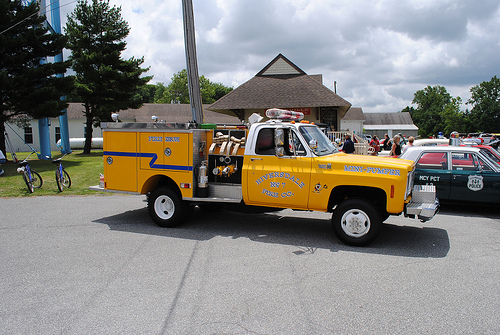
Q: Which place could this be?
A: It is a road.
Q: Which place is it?
A: It is a road.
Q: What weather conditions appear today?
A: It is cloudy.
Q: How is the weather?
A: It is cloudy.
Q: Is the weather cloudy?
A: Yes, it is cloudy.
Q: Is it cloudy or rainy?
A: It is cloudy.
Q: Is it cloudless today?
A: No, it is cloudy.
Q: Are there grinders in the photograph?
A: No, there are no grinders.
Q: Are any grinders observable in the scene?
A: No, there are no grinders.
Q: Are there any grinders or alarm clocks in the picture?
A: No, there are no grinders or alarm clocks.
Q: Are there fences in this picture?
A: No, there are no fences.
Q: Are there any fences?
A: No, there are no fences.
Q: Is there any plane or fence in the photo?
A: No, there are no fences or airplanes.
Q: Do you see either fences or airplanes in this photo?
A: No, there are no fences or airplanes.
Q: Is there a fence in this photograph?
A: No, there are no fences.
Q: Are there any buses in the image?
A: No, there are no buses.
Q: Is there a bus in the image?
A: No, there are no buses.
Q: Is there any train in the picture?
A: No, there are no trains.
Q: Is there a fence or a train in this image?
A: No, there are no trains or fences.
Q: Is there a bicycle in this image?
A: Yes, there is a bicycle.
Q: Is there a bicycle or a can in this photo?
A: Yes, there is a bicycle.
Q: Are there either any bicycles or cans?
A: Yes, there is a bicycle.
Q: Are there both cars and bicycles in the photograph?
A: Yes, there are both a bicycle and a car.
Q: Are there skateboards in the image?
A: No, there are no skateboards.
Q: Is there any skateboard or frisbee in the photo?
A: No, there are no skateboards or frisbees.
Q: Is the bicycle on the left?
A: Yes, the bicycle is on the left of the image.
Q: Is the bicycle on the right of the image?
A: No, the bicycle is on the left of the image.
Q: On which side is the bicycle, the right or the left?
A: The bicycle is on the left of the image.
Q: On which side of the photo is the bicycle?
A: The bicycle is on the left of the image.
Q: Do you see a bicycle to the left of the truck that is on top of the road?
A: Yes, there is a bicycle to the left of the truck.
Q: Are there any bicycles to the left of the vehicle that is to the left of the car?
A: Yes, there is a bicycle to the left of the truck.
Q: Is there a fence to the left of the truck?
A: No, there is a bicycle to the left of the truck.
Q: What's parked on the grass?
A: The bicycle is parked on the grass.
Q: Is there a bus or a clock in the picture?
A: No, there are no buses or clocks.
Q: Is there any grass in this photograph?
A: Yes, there is grass.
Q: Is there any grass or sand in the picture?
A: Yes, there is grass.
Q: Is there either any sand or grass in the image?
A: Yes, there is grass.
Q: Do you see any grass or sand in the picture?
A: Yes, there is grass.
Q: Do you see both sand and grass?
A: No, there is grass but no sand.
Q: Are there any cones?
A: No, there are no cones.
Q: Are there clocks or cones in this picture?
A: No, there are no cones or clocks.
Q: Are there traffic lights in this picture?
A: No, there are no traffic lights.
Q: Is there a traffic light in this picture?
A: No, there are no traffic lights.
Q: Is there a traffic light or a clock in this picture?
A: No, there are no traffic lights or clocks.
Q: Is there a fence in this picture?
A: No, there are no fences.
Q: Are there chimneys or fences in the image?
A: No, there are no fences or chimneys.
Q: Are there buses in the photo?
A: No, there are no buses.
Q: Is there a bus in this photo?
A: No, there are no buses.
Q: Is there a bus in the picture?
A: No, there are no buses.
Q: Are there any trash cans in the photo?
A: No, there are no trash cans.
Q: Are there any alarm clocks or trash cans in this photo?
A: No, there are no trash cans or alarm clocks.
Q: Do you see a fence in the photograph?
A: No, there are no fences.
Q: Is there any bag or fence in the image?
A: No, there are no fences or bags.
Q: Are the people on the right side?
A: Yes, the people are on the right of the image.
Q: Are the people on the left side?
A: No, the people are on the right of the image.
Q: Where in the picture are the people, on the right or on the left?
A: The people are on the right of the image.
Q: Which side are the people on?
A: The people are on the right of the image.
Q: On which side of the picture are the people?
A: The people are on the right of the image.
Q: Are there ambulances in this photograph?
A: No, there are no ambulances.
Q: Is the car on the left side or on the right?
A: The car is on the right of the image.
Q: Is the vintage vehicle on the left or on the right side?
A: The car is on the right of the image.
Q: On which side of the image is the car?
A: The car is on the right of the image.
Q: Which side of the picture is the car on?
A: The car is on the right of the image.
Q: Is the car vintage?
A: Yes, the car is vintage.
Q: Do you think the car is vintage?
A: Yes, the car is vintage.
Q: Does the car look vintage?
A: Yes, the car is vintage.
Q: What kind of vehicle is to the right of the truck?
A: The vehicle is a car.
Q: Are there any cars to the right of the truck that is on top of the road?
A: Yes, there is a car to the right of the truck.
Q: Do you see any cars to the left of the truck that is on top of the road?
A: No, the car is to the right of the truck.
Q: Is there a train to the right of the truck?
A: No, there is a car to the right of the truck.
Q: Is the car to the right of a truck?
A: Yes, the car is to the right of a truck.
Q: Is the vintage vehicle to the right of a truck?
A: Yes, the car is to the right of a truck.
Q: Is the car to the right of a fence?
A: No, the car is to the right of a truck.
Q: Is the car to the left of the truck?
A: No, the car is to the right of the truck.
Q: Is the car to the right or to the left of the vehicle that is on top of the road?
A: The car is to the right of the truck.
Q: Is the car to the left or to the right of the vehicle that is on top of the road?
A: The car is to the right of the truck.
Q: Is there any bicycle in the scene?
A: Yes, there is a bicycle.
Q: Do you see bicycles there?
A: Yes, there is a bicycle.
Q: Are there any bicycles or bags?
A: Yes, there is a bicycle.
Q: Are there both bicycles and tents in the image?
A: No, there is a bicycle but no tents.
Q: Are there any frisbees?
A: No, there are no frisbees.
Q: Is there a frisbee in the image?
A: No, there are no frisbees.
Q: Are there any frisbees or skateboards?
A: No, there are no frisbees or skateboards.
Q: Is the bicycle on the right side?
A: No, the bicycle is on the left of the image.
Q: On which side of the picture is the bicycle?
A: The bicycle is on the left of the image.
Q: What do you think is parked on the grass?
A: The bicycle is parked on the grass.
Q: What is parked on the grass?
A: The bicycle is parked on the grass.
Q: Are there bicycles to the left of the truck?
A: Yes, there is a bicycle to the left of the truck.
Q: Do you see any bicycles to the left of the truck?
A: Yes, there is a bicycle to the left of the truck.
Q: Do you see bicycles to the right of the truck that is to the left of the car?
A: No, the bicycle is to the left of the truck.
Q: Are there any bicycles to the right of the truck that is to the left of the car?
A: No, the bicycle is to the left of the truck.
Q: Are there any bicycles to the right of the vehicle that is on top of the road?
A: No, the bicycle is to the left of the truck.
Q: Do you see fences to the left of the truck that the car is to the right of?
A: No, there is a bicycle to the left of the truck.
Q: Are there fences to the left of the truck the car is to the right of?
A: No, there is a bicycle to the left of the truck.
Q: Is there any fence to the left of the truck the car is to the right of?
A: No, there is a bicycle to the left of the truck.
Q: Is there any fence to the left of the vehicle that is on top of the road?
A: No, there is a bicycle to the left of the truck.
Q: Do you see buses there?
A: No, there are no buses.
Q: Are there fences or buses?
A: No, there are no buses or fences.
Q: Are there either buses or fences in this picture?
A: No, there are no buses or fences.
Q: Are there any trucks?
A: Yes, there is a truck.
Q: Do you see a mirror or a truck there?
A: Yes, there is a truck.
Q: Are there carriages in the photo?
A: No, there are no carriages.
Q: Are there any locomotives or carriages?
A: No, there are no carriages or locomotives.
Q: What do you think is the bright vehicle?
A: The vehicle is a truck.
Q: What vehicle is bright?
A: The vehicle is a truck.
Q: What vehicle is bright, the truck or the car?
A: The truck is bright.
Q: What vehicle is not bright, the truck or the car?
A: The car is not bright.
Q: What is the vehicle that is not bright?
A: The vehicle is a car.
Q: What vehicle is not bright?
A: The vehicle is a car.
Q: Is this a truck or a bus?
A: This is a truck.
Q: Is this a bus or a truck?
A: This is a truck.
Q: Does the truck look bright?
A: Yes, the truck is bright.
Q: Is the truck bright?
A: Yes, the truck is bright.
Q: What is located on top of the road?
A: The truck is on top of the road.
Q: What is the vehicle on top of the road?
A: The vehicle is a truck.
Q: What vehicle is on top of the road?
A: The vehicle is a truck.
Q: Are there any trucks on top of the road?
A: Yes, there is a truck on top of the road.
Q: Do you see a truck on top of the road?
A: Yes, there is a truck on top of the road.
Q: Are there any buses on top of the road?
A: No, there is a truck on top of the road.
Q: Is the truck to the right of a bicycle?
A: Yes, the truck is to the right of a bicycle.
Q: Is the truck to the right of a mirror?
A: No, the truck is to the right of a bicycle.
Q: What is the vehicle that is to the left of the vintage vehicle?
A: The vehicle is a truck.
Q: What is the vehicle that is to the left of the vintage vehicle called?
A: The vehicle is a truck.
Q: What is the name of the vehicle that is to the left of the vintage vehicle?
A: The vehicle is a truck.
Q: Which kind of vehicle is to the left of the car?
A: The vehicle is a truck.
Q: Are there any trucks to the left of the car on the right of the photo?
A: Yes, there is a truck to the left of the car.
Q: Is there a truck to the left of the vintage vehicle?
A: Yes, there is a truck to the left of the car.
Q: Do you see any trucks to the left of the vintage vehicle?
A: Yes, there is a truck to the left of the car.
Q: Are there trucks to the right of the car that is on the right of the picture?
A: No, the truck is to the left of the car.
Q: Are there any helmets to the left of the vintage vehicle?
A: No, there is a truck to the left of the car.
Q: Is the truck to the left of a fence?
A: No, the truck is to the left of the car.